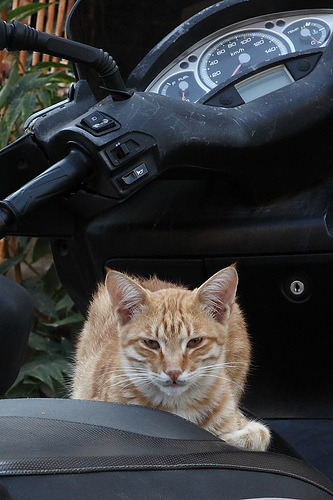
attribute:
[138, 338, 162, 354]
eye — looking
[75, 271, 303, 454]
cat — orange, old, white, brown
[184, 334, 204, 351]
eye — looking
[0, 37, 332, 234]
handle bar — black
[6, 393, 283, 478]
seat — black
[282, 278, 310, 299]
key hole — silver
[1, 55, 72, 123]
leaves — green